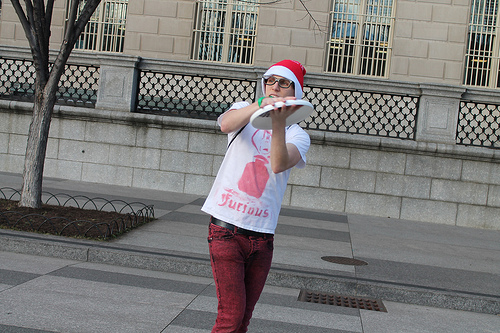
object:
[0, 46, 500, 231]
wall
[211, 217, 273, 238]
belt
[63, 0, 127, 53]
windows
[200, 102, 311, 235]
shirt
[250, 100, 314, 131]
frisbee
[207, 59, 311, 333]
boy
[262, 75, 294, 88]
eyeglasses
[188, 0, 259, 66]
window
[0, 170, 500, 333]
road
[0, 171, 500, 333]
curb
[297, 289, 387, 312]
rail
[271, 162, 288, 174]
elbow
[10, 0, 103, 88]
branches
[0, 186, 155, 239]
fence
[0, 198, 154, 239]
dirt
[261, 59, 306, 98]
head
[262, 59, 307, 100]
red cap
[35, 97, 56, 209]
edge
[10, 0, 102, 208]
tree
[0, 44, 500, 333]
blocks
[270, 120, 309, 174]
arm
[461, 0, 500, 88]
window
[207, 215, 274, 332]
pants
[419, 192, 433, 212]
part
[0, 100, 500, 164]
edge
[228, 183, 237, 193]
part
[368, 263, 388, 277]
part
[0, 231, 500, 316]
edge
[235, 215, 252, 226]
part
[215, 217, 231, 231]
part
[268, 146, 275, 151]
part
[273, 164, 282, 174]
part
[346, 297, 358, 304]
part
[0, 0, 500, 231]
building